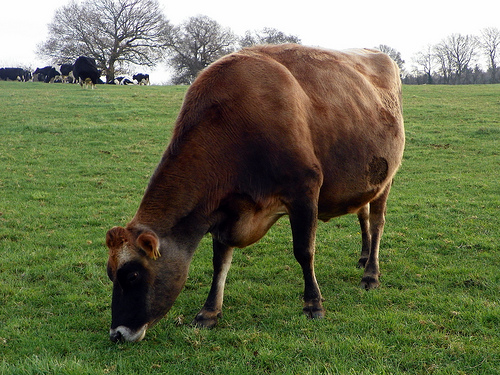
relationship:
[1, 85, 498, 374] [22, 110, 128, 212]
field has grass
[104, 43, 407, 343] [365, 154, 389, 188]
brown cow has sore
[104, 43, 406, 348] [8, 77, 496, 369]
brown cow grazing in grass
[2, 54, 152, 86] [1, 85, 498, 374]
cow group in field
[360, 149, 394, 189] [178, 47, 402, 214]
bald spot on cow fur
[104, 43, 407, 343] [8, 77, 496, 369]
brown cow eating grass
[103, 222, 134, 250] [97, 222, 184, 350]
bump on top of head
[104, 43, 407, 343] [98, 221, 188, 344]
brown cow has face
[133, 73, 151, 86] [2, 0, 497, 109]
cow in background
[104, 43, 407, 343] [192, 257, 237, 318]
brown cow has feet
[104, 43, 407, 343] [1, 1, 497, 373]
brown cow near camera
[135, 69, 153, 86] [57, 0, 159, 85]
cow near tree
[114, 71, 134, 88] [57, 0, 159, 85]
cow near tree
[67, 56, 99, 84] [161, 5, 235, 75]
cow near tree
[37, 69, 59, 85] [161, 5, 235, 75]
cow near tree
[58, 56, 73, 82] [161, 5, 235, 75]
cow near tree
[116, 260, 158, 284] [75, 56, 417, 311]
eye on cow